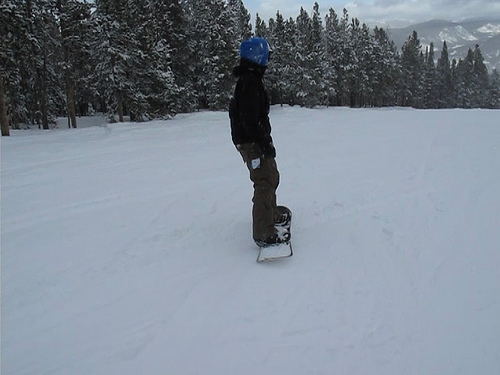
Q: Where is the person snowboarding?
A: On a snowy mountain.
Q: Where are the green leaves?
A: On the trees.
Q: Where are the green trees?
A: On the snowy hill.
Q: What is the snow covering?
A: The trees with the green leaves.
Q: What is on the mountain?
A: White snow.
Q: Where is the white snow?
A: On the mountain.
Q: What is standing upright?
A: The person.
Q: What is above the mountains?
A: The grey sky.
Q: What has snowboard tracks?
A: The white snow.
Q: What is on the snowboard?
A: The snowboarder.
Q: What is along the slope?
A: The forest of pines.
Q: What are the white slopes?
A: Snowy.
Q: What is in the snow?
A: Tracks.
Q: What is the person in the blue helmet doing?
A: Snowboarding.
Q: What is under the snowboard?
A: Snow.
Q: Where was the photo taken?
A: Ski slopes.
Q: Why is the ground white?
A: Snow.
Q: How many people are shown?
A: One.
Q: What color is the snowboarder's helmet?
A: Blue.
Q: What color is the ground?
A: White.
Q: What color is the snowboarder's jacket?
A: Black.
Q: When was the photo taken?
A: Daytime.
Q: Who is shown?
A: Snowboarder.